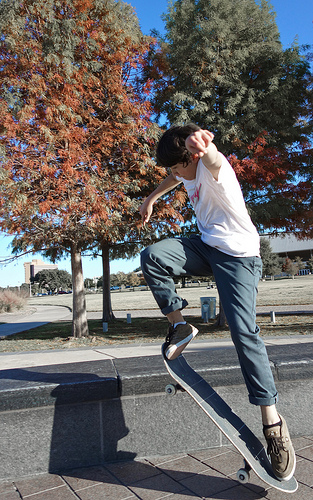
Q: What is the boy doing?
A: Skating.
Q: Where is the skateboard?
A: In the air.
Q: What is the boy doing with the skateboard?
A: A trick.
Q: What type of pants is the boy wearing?
A: Jeans.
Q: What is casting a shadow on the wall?
A: Skateboard.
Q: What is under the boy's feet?
A: Skateboard.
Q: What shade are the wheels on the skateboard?
A: White.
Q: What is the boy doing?
A: Skateboarding.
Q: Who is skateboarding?
A: A boy.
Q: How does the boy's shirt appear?
A: White t-shirt.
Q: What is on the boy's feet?
A: Brown shoes.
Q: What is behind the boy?
A: Two large trees.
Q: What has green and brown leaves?
A: A tree.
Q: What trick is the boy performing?
A: A skateboard jump.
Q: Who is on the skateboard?
A: A boy.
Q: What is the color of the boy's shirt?
A: White.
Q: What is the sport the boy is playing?
A: Skateboard.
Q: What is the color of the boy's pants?
A: Blue.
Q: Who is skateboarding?
A: The boy.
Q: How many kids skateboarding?
A: One.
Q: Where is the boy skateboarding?
A: At the park.